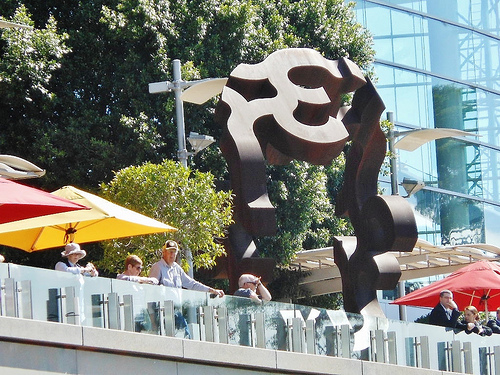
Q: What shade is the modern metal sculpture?
A: Brown.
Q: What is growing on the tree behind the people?
A: Leaves.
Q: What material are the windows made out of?
A: Glass.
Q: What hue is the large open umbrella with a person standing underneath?
A: Yellow.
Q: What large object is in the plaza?
A: A sculpture.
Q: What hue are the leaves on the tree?
A: Green.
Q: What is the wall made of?
A: Glass.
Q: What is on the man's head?
A: Hat.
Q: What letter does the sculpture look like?
A: E.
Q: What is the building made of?
A: Glass.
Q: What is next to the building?
A: Trees.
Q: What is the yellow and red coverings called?
A: Umbrellas.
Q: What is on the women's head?
A: Hat.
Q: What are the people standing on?
A: Bridge.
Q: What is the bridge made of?
A: Concrete.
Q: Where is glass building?
A: On the right.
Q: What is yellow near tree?
A: Umbrella.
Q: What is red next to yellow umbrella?
A: Umbrella.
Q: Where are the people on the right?
A: Front of red umbrella.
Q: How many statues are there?
A: One.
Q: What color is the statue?
A: Black.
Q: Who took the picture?
A: A friend.